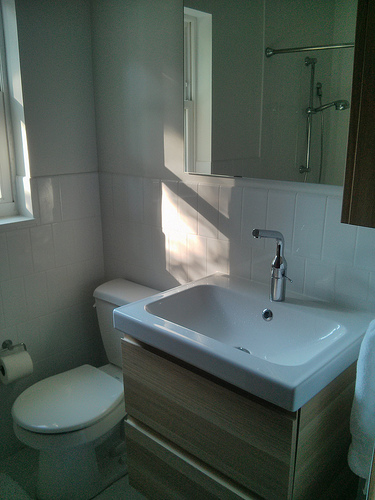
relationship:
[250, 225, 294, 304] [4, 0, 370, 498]
bathroom faucet in bathroom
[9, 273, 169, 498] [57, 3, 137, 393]
toilet in corner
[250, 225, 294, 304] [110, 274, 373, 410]
bathroom faucet on sink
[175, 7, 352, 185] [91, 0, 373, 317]
mirror on wall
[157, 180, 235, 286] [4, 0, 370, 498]
light in bathroom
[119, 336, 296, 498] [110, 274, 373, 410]
drawer under sink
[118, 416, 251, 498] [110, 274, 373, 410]
drawer under sink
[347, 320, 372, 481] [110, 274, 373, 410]
towel next to sink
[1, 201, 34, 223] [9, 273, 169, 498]
sill above toilet